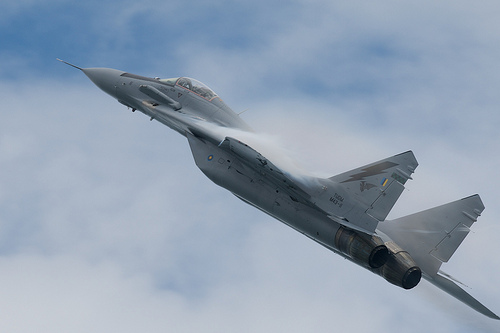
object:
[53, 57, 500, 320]
jet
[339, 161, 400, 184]
lightning bolt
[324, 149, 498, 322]
tail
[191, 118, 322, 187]
smoke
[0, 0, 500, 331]
sky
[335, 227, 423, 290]
engine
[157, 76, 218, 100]
glass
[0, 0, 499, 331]
cloud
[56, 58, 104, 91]
nose